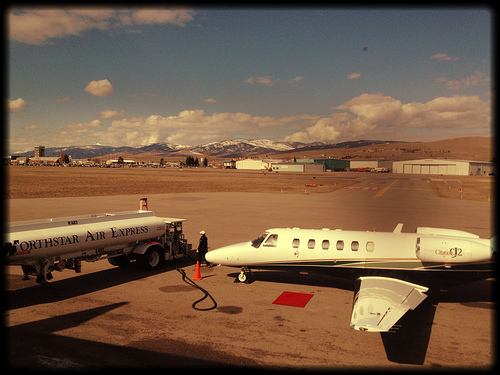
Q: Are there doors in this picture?
A: Yes, there are doors.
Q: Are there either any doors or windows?
A: Yes, there are doors.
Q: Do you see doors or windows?
A: Yes, there are doors.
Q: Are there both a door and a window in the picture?
A: Yes, there are both a door and a window.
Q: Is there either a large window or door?
A: Yes, there are large doors.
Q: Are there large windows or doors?
A: Yes, there are large doors.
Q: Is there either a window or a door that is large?
A: Yes, the doors are large.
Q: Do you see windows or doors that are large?
A: Yes, the doors are large.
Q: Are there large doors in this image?
A: Yes, there are large doors.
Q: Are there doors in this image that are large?
A: Yes, there are doors that are large.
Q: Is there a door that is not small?
A: Yes, there are large doors.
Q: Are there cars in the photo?
A: No, there are no cars.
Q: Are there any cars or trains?
A: No, there are no cars or trains.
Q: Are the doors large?
A: Yes, the doors are large.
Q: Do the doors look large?
A: Yes, the doors are large.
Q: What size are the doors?
A: The doors are large.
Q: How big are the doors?
A: The doors are large.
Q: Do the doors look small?
A: No, the doors are large.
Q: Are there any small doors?
A: No, there are doors but they are large.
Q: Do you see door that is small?
A: No, there are doors but they are large.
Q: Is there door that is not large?
A: No, there are doors but they are large.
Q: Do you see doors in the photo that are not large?
A: No, there are doors but they are large.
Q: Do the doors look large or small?
A: The doors are large.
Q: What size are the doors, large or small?
A: The doors are large.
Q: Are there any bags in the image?
A: No, there are no bags.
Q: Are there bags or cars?
A: No, there are no bags or cars.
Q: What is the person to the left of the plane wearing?
A: The person is wearing a hat.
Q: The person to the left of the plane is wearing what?
A: The person is wearing a hat.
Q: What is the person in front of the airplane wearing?
A: The person is wearing a hat.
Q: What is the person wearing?
A: The person is wearing a hat.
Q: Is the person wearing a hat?
A: Yes, the person is wearing a hat.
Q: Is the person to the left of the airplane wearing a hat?
A: Yes, the person is wearing a hat.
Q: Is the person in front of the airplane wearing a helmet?
A: No, the person is wearing a hat.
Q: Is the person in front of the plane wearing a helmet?
A: No, the person is wearing a hat.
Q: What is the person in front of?
A: The person is in front of the airplane.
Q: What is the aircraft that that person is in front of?
A: The aircraft is an airplane.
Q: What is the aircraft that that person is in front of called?
A: The aircraft is an airplane.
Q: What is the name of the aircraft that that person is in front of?
A: The aircraft is an airplane.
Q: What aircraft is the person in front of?
A: The person is in front of the airplane.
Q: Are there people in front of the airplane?
A: Yes, there is a person in front of the airplane.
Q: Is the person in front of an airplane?
A: Yes, the person is in front of an airplane.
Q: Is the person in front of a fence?
A: No, the person is in front of an airplane.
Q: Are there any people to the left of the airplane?
A: Yes, there is a person to the left of the airplane.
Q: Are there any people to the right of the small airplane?
A: No, the person is to the left of the airplane.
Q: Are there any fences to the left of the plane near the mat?
A: No, there is a person to the left of the plane.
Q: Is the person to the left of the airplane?
A: Yes, the person is to the left of the airplane.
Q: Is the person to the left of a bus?
A: No, the person is to the left of the airplane.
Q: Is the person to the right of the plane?
A: No, the person is to the left of the plane.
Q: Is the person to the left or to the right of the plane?
A: The person is to the left of the plane.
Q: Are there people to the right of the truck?
A: Yes, there is a person to the right of the truck.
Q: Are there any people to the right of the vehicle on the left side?
A: Yes, there is a person to the right of the truck.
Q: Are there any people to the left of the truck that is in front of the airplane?
A: No, the person is to the right of the truck.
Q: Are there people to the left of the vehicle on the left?
A: No, the person is to the right of the truck.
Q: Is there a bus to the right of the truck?
A: No, there is a person to the right of the truck.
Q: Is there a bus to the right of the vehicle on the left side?
A: No, there is a person to the right of the truck.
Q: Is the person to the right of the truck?
A: Yes, the person is to the right of the truck.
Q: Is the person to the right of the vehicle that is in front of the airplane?
A: Yes, the person is to the right of the truck.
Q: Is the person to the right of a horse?
A: No, the person is to the right of the truck.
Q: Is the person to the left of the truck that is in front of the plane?
A: No, the person is to the right of the truck.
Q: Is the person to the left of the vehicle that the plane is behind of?
A: No, the person is to the right of the truck.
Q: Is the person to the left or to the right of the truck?
A: The person is to the right of the truck.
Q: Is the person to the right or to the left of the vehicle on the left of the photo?
A: The person is to the right of the truck.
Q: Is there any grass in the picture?
A: Yes, there is grass.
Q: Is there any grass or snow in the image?
A: Yes, there is grass.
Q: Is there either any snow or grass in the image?
A: Yes, there is grass.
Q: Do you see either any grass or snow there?
A: Yes, there is grass.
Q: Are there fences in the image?
A: No, there are no fences.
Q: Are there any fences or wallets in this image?
A: No, there are no fences or wallets.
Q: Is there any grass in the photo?
A: Yes, there is grass.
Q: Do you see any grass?
A: Yes, there is grass.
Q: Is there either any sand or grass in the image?
A: Yes, there is grass.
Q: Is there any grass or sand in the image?
A: Yes, there is grass.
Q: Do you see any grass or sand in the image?
A: Yes, there is grass.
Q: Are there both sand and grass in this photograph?
A: No, there is grass but no sand.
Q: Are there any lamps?
A: No, there are no lamps.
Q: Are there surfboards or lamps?
A: No, there are no lamps or surfboards.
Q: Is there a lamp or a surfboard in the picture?
A: No, there are no lamps or surfboards.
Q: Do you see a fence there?
A: No, there are no fences.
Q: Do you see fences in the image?
A: No, there are no fences.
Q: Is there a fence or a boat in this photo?
A: No, there are no fences or boats.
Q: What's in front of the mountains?
A: The buildings are in front of the mountains.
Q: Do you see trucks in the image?
A: Yes, there is a truck.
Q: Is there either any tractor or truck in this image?
A: Yes, there is a truck.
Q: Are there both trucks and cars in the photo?
A: No, there is a truck but no cars.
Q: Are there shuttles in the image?
A: No, there are no shuttles.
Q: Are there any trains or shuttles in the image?
A: No, there are no shuttles or trains.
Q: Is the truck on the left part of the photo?
A: Yes, the truck is on the left of the image.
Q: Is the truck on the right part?
A: No, the truck is on the left of the image.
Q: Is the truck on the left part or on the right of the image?
A: The truck is on the left of the image.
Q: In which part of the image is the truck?
A: The truck is on the left of the image.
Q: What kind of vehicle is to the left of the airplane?
A: The vehicle is a truck.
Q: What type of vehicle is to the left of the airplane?
A: The vehicle is a truck.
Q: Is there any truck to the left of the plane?
A: Yes, there is a truck to the left of the plane.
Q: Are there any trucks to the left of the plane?
A: Yes, there is a truck to the left of the plane.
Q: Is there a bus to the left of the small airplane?
A: No, there is a truck to the left of the plane.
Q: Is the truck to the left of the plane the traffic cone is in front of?
A: Yes, the truck is to the left of the plane.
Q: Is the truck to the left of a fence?
A: No, the truck is to the left of the plane.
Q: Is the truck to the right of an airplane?
A: No, the truck is to the left of an airplane.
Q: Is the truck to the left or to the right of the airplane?
A: The truck is to the left of the airplane.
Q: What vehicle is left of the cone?
A: The vehicle is a truck.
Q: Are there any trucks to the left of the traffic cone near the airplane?
A: Yes, there is a truck to the left of the cone.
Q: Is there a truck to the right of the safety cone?
A: No, the truck is to the left of the safety cone.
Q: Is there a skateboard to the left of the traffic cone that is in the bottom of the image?
A: No, there is a truck to the left of the cone.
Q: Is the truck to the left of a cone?
A: Yes, the truck is to the left of a cone.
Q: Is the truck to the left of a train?
A: No, the truck is to the left of a cone.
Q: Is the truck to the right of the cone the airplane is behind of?
A: No, the truck is to the left of the cone.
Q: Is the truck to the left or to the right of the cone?
A: The truck is to the left of the cone.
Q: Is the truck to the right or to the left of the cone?
A: The truck is to the left of the cone.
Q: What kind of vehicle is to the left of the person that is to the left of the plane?
A: The vehicle is a truck.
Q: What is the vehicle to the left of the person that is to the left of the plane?
A: The vehicle is a truck.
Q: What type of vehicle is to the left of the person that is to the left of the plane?
A: The vehicle is a truck.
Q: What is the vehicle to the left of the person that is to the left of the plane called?
A: The vehicle is a truck.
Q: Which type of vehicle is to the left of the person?
A: The vehicle is a truck.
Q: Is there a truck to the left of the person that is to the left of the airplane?
A: Yes, there is a truck to the left of the person.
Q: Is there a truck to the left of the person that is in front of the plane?
A: Yes, there is a truck to the left of the person.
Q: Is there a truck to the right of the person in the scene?
A: No, the truck is to the left of the person.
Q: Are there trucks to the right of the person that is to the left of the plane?
A: No, the truck is to the left of the person.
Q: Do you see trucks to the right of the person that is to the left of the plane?
A: No, the truck is to the left of the person.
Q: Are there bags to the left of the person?
A: No, there is a truck to the left of the person.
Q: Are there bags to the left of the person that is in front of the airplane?
A: No, there is a truck to the left of the person.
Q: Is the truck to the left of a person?
A: Yes, the truck is to the left of a person.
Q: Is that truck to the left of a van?
A: No, the truck is to the left of a person.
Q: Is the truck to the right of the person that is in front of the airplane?
A: No, the truck is to the left of the person.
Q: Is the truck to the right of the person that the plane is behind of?
A: No, the truck is to the left of the person.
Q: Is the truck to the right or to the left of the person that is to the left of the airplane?
A: The truck is to the left of the person.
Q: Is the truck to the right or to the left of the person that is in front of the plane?
A: The truck is to the left of the person.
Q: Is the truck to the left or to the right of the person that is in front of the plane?
A: The truck is to the left of the person.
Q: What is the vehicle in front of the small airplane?
A: The vehicle is a truck.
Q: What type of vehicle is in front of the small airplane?
A: The vehicle is a truck.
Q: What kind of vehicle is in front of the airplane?
A: The vehicle is a truck.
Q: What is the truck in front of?
A: The truck is in front of the airplane.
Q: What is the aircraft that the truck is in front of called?
A: The aircraft is an airplane.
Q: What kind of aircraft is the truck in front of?
A: The truck is in front of the airplane.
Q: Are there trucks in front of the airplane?
A: Yes, there is a truck in front of the airplane.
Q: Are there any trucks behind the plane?
A: No, the truck is in front of the plane.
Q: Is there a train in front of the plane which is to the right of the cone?
A: No, there is a truck in front of the airplane.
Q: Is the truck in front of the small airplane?
A: Yes, the truck is in front of the plane.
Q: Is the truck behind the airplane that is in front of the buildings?
A: No, the truck is in front of the airplane.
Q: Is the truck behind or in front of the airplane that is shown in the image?
A: The truck is in front of the airplane.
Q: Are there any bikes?
A: No, there are no bikes.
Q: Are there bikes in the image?
A: No, there are no bikes.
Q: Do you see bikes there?
A: No, there are no bikes.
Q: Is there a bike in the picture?
A: No, there are no bikes.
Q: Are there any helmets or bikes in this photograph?
A: No, there are no bikes or helmets.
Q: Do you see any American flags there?
A: No, there are no American flags.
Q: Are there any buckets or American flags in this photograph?
A: No, there are no American flags or buckets.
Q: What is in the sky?
A: The clouds are in the sky.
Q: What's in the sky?
A: The clouds are in the sky.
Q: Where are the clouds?
A: The clouds are in the sky.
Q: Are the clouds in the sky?
A: Yes, the clouds are in the sky.